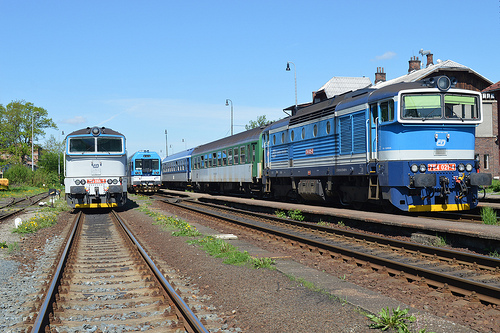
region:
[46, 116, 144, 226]
train on a track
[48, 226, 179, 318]
tracks of a train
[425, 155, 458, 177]
license of a train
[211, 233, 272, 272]
patch of grass by tracks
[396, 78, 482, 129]
front windows of a train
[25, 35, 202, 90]
blue sky in the distance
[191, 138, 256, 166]
side windows of a train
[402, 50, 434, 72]
chimneys on a building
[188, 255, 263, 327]
gravel in between tracks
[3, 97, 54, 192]
green leaves on a tree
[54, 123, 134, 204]
gray train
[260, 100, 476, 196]
blue train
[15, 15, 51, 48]
white clouds in blue sky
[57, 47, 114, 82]
white clouds in blue sky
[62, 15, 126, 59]
white clouds in blue sky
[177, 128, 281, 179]
green and white train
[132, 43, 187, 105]
white clouds in blue sky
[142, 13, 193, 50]
white clouds in blue sky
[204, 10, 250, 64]
white clouds in blue sky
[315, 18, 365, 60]
white clouds in blue sky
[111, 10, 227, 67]
blue sky above the trains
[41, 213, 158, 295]
track in front of train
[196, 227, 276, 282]
grass in between tracks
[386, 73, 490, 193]
front of the train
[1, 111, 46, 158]
tree in the distance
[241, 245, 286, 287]
patch of grass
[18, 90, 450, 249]
three different trains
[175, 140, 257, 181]
windows on side of train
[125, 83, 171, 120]
cloud in the sky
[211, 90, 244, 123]
light pole in the distance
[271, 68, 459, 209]
blue and white train engine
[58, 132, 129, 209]
train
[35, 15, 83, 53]
white clouds in blue sky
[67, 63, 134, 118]
white clouds in blue sky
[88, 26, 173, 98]
white clouds in blue sky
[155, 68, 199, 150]
white clouds in blue sky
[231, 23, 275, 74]
white clouds in blue sky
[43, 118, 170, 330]
a train on the track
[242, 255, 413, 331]
weeds growing on the side of train tracks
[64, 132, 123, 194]
two windows on the front of the train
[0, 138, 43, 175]
a building next to the train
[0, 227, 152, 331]
gravel is under and near the track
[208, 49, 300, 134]
lights hanging above the train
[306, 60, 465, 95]
the roof is white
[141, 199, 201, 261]
yellow flowers growing out of the ground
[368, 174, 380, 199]
a short ladder on a train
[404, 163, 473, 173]
four lights on the front of a train